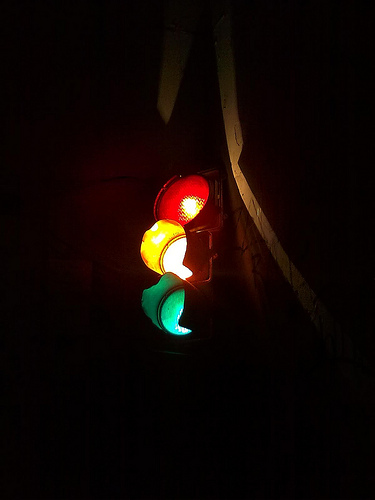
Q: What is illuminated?
A: Red, yellow, and green lights.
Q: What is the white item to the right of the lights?
A: Tape.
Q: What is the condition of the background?
A: It is black.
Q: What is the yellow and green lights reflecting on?
A: Covers above them.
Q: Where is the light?
A: Pole.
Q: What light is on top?
A: Red.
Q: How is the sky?
A: Dark.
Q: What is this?
A: Traffic lights.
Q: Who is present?
A: Nobody.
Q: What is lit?
A: Lights.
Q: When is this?
A: Night.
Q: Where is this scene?
A: At an intersection.